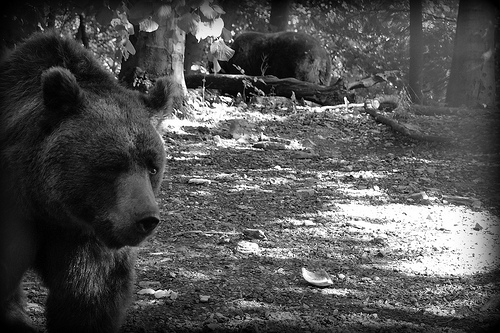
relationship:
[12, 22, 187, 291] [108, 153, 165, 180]
bear has eyes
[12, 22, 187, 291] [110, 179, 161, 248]
bear has muzzle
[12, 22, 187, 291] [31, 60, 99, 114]
bear has ear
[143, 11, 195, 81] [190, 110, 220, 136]
trees have roots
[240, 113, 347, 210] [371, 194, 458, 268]
ground has sunlight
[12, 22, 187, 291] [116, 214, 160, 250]
bear has snout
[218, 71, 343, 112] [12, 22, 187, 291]
log behind bear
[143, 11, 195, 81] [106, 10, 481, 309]
trees in forrest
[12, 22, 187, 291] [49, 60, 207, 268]
bear has face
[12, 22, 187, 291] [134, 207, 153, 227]
bear has nose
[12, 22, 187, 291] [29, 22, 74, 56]
bear has back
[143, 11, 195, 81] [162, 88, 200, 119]
trees have base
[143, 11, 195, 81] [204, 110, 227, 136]
trees have leaves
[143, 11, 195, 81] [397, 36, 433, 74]
trees have trunk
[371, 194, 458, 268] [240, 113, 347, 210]
sunlight on ground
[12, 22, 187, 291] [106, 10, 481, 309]
bear in forrest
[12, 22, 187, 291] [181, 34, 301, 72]
bear on background